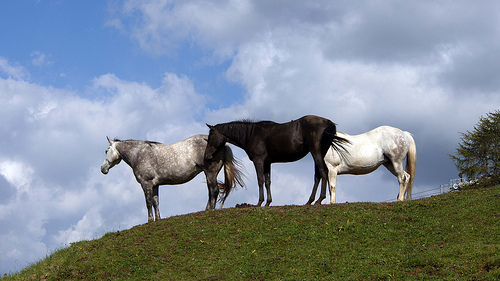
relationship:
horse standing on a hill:
[201, 116, 336, 206] [14, 214, 497, 280]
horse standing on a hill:
[99, 130, 208, 219] [14, 214, 497, 280]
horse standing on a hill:
[336, 122, 422, 200] [14, 214, 497, 280]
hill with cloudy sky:
[14, 214, 497, 280] [6, 5, 495, 111]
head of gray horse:
[96, 127, 132, 175] [99, 130, 208, 219]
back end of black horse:
[272, 98, 337, 200] [201, 116, 336, 206]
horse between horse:
[201, 116, 336, 206] [321, 124, 414, 200]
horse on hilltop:
[321, 124, 414, 200] [14, 214, 497, 280]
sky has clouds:
[6, 5, 495, 111] [160, 13, 479, 112]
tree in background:
[442, 114, 498, 181] [6, 5, 495, 111]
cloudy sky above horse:
[6, 5, 495, 111] [321, 124, 414, 200]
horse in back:
[336, 122, 422, 200] [323, 83, 431, 198]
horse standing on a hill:
[321, 124, 414, 200] [14, 214, 497, 280]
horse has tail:
[99, 130, 208, 219] [220, 146, 238, 205]